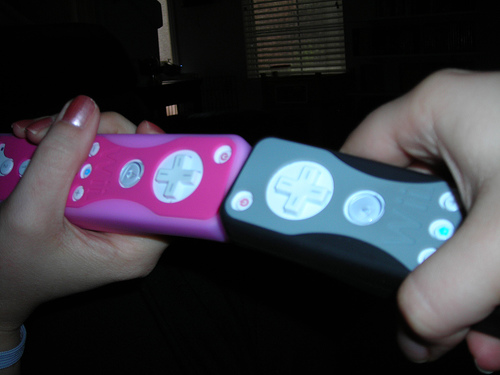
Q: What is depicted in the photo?
A: A woman's hand.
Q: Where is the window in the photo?
A: In the back.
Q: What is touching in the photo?
A: Two game controls.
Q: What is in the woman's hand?
A: A pink game control.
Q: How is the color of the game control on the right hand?
A: Gray and black.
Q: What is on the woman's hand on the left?
A: A pink game controller.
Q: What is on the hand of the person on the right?
A: A black game controller.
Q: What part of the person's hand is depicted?
A: The finger.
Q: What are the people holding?
A: Game controllers.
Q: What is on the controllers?
A: Buttons.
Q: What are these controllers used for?
A: Play video game.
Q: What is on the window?
A: Shades.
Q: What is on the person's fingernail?
A: Nail polish.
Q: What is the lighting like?
A: Dark.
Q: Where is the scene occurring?
A: In a living room.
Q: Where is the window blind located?
A: Top middle of picture.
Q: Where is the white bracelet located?
A: Lower left corner on girls wrist.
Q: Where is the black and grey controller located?
A: Middle right in boys hand.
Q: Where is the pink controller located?
A: Middle left in girls hand.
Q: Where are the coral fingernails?
A: Left middle on the girls hand.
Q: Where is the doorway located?
A: Top slightly left of middle.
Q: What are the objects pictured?
A: Game controllers.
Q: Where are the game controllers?
A: In people's hands.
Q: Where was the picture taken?
A: Inside of a building.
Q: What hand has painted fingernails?
A: The hand on the left.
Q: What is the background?
A: A window.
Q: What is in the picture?
A: Video game controls.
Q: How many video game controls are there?
A: Two.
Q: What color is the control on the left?
A: Pink.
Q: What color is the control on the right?
A: Blue.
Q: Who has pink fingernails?
A: The person on the left.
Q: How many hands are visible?
A: Two.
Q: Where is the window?
A: Back of the photo.